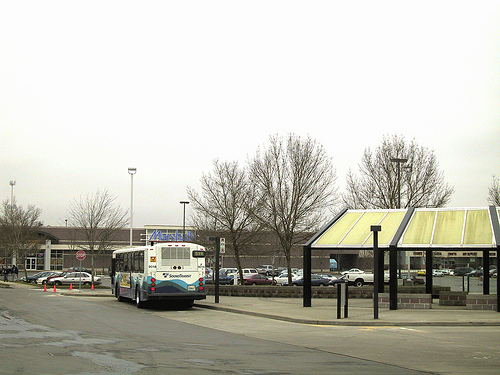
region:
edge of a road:
[264, 295, 299, 339]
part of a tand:
[301, 269, 312, 301]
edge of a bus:
[155, 279, 183, 300]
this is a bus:
[109, 234, 210, 308]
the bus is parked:
[110, 236, 210, 307]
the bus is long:
[108, 237, 210, 312]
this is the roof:
[313, 205, 482, 243]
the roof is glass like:
[428, 212, 471, 236]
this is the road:
[201, 310, 309, 373]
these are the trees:
[215, 150, 310, 244]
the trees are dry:
[226, 147, 320, 221]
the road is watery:
[98, 340, 132, 372]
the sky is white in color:
[113, 70, 269, 131]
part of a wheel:
[136, 300, 151, 308]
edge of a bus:
[163, 285, 193, 305]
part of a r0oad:
[200, 328, 219, 363]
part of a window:
[173, 245, 180, 252]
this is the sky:
[65, 34, 352, 119]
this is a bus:
[114, 237, 207, 318]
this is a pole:
[372, 213, 392, 296]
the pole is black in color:
[368, 232, 379, 283]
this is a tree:
[259, 130, 314, 244]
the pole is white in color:
[126, 175, 140, 246]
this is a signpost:
[73, 245, 88, 262]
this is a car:
[343, 262, 373, 284]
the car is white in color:
[342, 270, 367, 281]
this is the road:
[29, 296, 96, 369]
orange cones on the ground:
[34, 260, 109, 307]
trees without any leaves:
[168, 142, 354, 264]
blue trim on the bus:
[114, 268, 207, 320]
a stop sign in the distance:
[57, 225, 106, 291]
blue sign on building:
[133, 219, 208, 251]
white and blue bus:
[108, 232, 225, 297]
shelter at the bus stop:
[301, 202, 498, 314]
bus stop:
[211, 200, 498, 331]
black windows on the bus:
[113, 249, 145, 274]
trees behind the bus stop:
[184, 138, 434, 284]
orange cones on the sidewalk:
[45, 279, 96, 297]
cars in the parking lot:
[43, 254, 389, 289]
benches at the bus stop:
[375, 289, 493, 311]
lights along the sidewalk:
[8, 162, 402, 291]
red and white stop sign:
[75, 249, 88, 286]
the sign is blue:
[146, 224, 201, 249]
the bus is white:
[108, 229, 225, 323]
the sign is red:
[70, 236, 88, 261]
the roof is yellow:
[321, 196, 396, 272]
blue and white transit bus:
[105, 238, 210, 310]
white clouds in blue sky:
[44, 80, 78, 107]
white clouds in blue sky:
[165, 100, 204, 140]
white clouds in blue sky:
[51, 103, 105, 134]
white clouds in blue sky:
[151, 109, 202, 154]